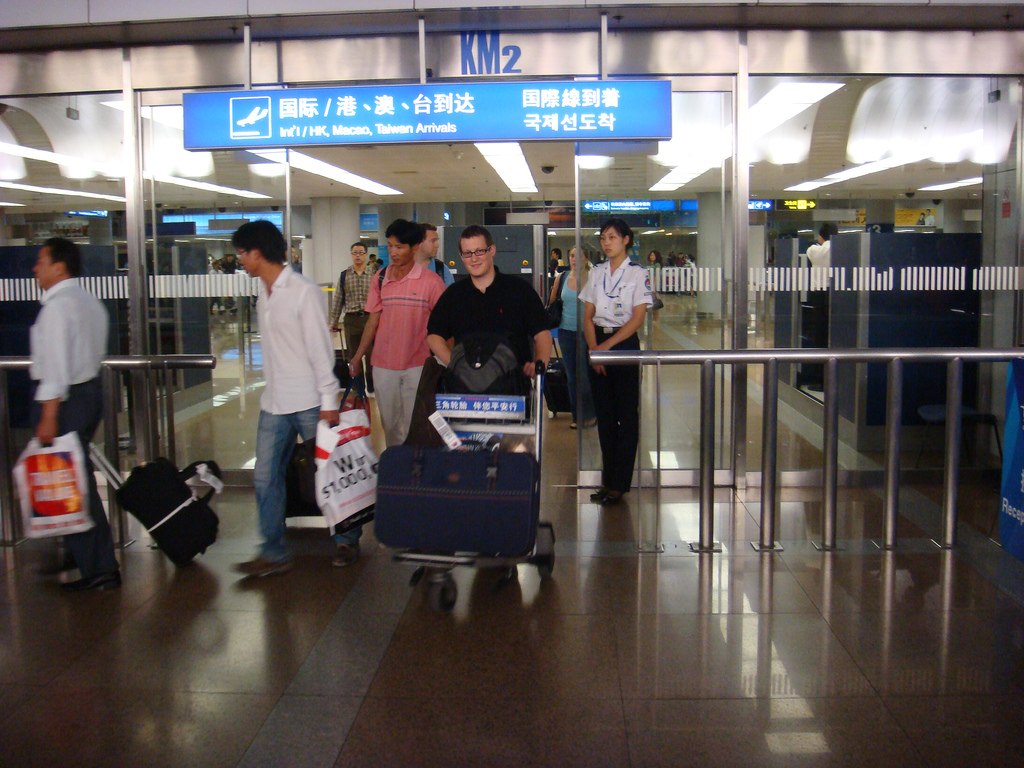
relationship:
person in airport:
[333, 230, 382, 355] [8, 9, 1014, 756]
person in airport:
[11, 234, 167, 583] [8, 9, 1014, 756]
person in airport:
[216, 220, 382, 590] [8, 9, 1014, 756]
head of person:
[438, 231, 500, 279] [419, 227, 554, 574]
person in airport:
[419, 227, 554, 574] [8, 9, 1014, 756]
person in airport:
[345, 212, 445, 446] [8, 9, 1014, 756]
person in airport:
[413, 230, 554, 469] [8, 9, 1014, 756]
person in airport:
[560, 211, 660, 503] [8, 9, 1014, 756]